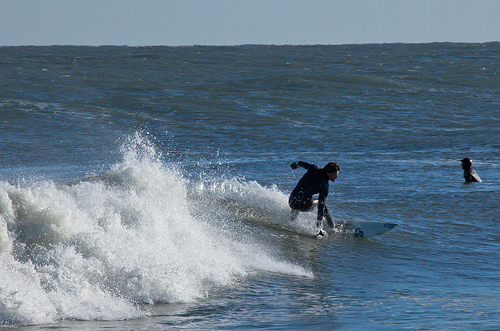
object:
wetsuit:
[287, 160, 329, 220]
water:
[2, 39, 499, 331]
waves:
[0, 125, 354, 331]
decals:
[353, 224, 397, 238]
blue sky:
[0, 0, 500, 45]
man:
[459, 157, 483, 185]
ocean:
[0, 40, 500, 331]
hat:
[459, 158, 472, 169]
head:
[459, 158, 472, 170]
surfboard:
[316, 217, 400, 240]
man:
[288, 160, 344, 240]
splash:
[0, 121, 327, 327]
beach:
[0, 42, 500, 328]